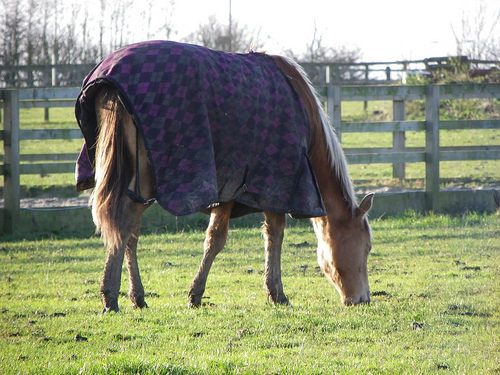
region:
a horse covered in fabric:
[75, 42, 373, 320]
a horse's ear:
[357, 190, 372, 217]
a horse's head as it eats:
[314, 212, 376, 306]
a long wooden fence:
[2, 83, 498, 223]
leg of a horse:
[185, 205, 231, 305]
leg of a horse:
[263, 210, 288, 309]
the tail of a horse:
[92, 99, 127, 251]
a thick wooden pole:
[424, 85, 442, 214]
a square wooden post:
[1, 88, 23, 238]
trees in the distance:
[0, 1, 362, 88]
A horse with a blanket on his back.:
[57, 25, 374, 310]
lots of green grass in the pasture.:
[0, 203, 499, 373]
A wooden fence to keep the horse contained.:
[1, 71, 496, 245]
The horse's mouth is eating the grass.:
[338, 290, 373, 305]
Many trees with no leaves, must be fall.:
[1, 0, 364, 84]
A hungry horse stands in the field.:
[54, 38, 391, 316]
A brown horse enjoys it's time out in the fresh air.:
[66, 40, 381, 310]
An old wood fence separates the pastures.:
[0, 80, 496, 219]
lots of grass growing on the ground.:
[2, 236, 496, 371]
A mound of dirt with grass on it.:
[397, 69, 494, 126]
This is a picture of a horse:
[77, 55, 422, 371]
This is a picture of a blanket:
[84, 41, 331, 246]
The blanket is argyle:
[92, 33, 346, 226]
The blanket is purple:
[80, 51, 382, 288]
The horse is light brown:
[92, 108, 430, 324]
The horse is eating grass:
[298, 190, 403, 369]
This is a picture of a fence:
[43, 64, 470, 204]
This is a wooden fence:
[330, 66, 497, 242]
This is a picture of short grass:
[228, 282, 453, 372]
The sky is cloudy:
[247, 20, 397, 130]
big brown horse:
[89, 37, 375, 307]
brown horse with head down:
[85, 39, 373, 310]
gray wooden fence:
[1, 80, 497, 225]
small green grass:
[1, 206, 495, 370]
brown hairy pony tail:
[93, 77, 133, 248]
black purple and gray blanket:
[75, 38, 323, 216]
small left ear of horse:
[352, 191, 375, 221]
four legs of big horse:
[96, 151, 287, 311]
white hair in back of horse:
[278, 48, 368, 228]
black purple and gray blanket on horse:
[73, 39, 326, 219]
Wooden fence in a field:
[3, 78, 494, 236]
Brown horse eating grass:
[74, 29, 373, 306]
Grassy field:
[0, 207, 499, 370]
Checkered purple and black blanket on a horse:
[71, 39, 325, 218]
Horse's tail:
[90, 85, 136, 252]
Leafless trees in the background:
[1, 0, 496, 86]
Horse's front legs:
[180, 205, 293, 305]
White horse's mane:
[284, 55, 361, 204]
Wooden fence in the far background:
[1, 62, 498, 82]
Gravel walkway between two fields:
[0, 178, 494, 204]